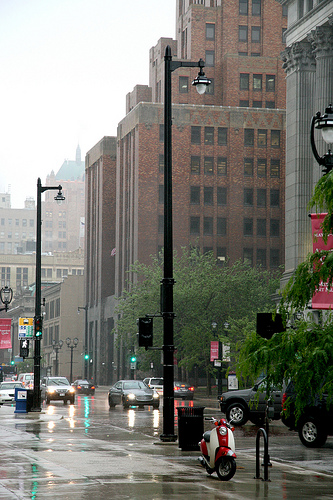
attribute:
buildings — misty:
[0, 139, 123, 360]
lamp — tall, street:
[17, 158, 75, 428]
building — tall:
[85, 1, 283, 386]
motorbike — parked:
[196, 415, 237, 482]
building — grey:
[278, 1, 331, 327]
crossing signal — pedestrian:
[19, 338, 29, 359]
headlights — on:
[47, 388, 74, 395]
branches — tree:
[228, 323, 332, 429]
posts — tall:
[32, 44, 210, 442]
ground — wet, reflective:
[0, 389, 331, 499]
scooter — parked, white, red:
[196, 417, 239, 481]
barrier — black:
[255, 427, 269, 480]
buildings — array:
[0, 0, 331, 385]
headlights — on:
[126, 393, 158, 401]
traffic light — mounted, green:
[33, 315, 43, 340]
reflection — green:
[29, 462, 38, 499]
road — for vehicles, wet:
[45, 389, 332, 482]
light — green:
[82, 395, 90, 433]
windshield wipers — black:
[52, 379, 66, 386]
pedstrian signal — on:
[19, 338, 29, 348]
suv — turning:
[218, 375, 290, 428]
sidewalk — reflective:
[1, 404, 332, 499]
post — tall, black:
[30, 178, 42, 412]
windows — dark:
[188, 185, 279, 238]